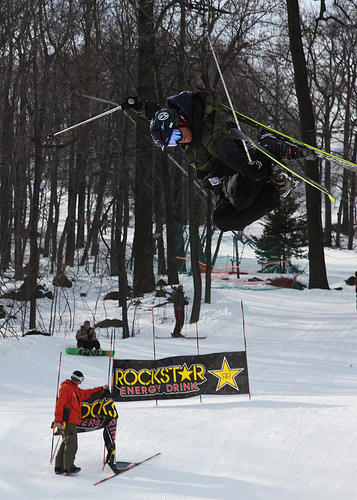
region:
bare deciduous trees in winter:
[3, 2, 98, 318]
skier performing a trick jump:
[39, 34, 356, 236]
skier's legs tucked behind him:
[209, 90, 355, 202]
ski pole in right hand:
[39, 80, 167, 157]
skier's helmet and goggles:
[143, 103, 200, 156]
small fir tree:
[245, 193, 312, 278]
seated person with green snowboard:
[58, 315, 121, 361]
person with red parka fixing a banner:
[52, 358, 122, 492]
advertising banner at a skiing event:
[106, 347, 263, 410]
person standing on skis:
[147, 279, 209, 343]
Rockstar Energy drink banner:
[111, 297, 258, 409]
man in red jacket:
[54, 352, 84, 484]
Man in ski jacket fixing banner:
[49, 349, 153, 483]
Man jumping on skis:
[80, 62, 354, 244]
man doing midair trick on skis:
[50, 38, 354, 225]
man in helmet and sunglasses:
[98, 96, 231, 165]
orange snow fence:
[183, 253, 336, 294]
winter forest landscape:
[18, 191, 213, 283]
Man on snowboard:
[61, 313, 121, 359]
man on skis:
[149, 277, 218, 339]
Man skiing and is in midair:
[45, 40, 355, 257]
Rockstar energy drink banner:
[106, 346, 253, 399]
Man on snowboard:
[60, 314, 119, 365]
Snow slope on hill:
[266, 303, 339, 420]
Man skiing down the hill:
[161, 284, 210, 344]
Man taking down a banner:
[46, 367, 151, 489]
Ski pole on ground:
[84, 447, 170, 485]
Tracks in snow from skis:
[267, 264, 355, 383]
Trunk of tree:
[307, 245, 343, 301]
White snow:
[223, 412, 281, 466]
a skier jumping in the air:
[123, 80, 331, 236]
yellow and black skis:
[215, 95, 356, 205]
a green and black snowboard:
[62, 345, 123, 355]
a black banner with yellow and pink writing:
[97, 340, 252, 402]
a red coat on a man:
[48, 375, 84, 423]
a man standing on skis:
[162, 280, 202, 341]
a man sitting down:
[71, 316, 108, 352]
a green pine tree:
[263, 192, 314, 275]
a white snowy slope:
[2, 255, 352, 498]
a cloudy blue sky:
[9, 1, 353, 77]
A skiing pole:
[41, 88, 136, 168]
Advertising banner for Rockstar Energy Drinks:
[113, 351, 249, 397]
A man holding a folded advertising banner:
[42, 375, 165, 489]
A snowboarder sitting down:
[53, 322, 130, 360]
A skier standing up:
[142, 270, 217, 350]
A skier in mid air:
[39, 27, 355, 252]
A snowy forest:
[0, 147, 156, 319]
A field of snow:
[206, 401, 355, 498]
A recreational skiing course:
[3, 182, 353, 498]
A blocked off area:
[158, 240, 337, 298]